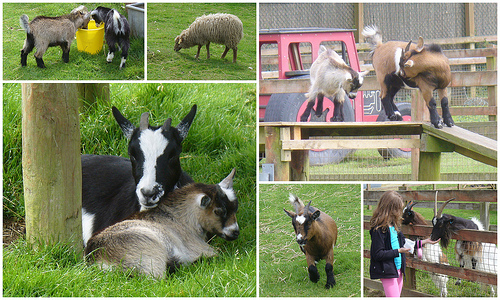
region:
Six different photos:
[6, 7, 486, 288]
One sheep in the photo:
[147, 2, 252, 74]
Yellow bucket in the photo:
[66, 15, 111, 55]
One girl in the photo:
[365, 185, 421, 295]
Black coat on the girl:
[367, 211, 407, 276]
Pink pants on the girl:
[375, 266, 410, 291]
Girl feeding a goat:
[365, 185, 445, 291]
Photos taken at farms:
[0, 10, 491, 290]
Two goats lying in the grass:
[61, 100, 246, 275]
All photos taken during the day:
[0, 2, 494, 291]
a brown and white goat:
[282, 188, 340, 290]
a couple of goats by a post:
[18, 85, 238, 275]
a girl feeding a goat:
[362, 186, 459, 297]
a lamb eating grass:
[152, 6, 257, 77]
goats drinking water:
[12, 0, 136, 75]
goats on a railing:
[289, 23, 452, 133]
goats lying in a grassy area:
[12, 103, 246, 285]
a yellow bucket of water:
[75, 20, 103, 57]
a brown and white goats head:
[282, 210, 322, 246]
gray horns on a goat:
[139, 116, 174, 135]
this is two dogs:
[10, 3, 142, 74]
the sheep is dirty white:
[160, 6, 247, 68]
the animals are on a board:
[281, 14, 471, 151]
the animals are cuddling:
[50, 90, 248, 287]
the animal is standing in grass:
[271, 182, 345, 299]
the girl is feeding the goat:
[367, 179, 497, 291]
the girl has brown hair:
[369, 186, 427, 297]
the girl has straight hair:
[367, 178, 432, 278]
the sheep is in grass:
[150, 12, 253, 65]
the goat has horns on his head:
[96, 89, 204, 149]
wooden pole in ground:
[18, 76, 87, 253]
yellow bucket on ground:
[77, 21, 105, 56]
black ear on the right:
[104, 106, 135, 139]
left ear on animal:
[180, 103, 196, 136]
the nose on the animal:
[136, 188, 160, 200]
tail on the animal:
[14, 14, 34, 33]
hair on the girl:
[370, 190, 399, 229]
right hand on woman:
[395, 247, 411, 259]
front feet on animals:
[308, 265, 334, 285]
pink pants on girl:
[380, 270, 409, 298]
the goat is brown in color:
[361, 36, 468, 133]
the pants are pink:
[382, 276, 407, 298]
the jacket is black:
[368, 226, 411, 274]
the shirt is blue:
[384, 229, 403, 268]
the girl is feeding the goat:
[370, 197, 425, 298]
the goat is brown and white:
[107, 190, 241, 290]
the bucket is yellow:
[81, 22, 108, 60]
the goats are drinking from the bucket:
[25, 1, 135, 77]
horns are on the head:
[120, 111, 181, 133]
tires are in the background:
[274, 87, 423, 164]